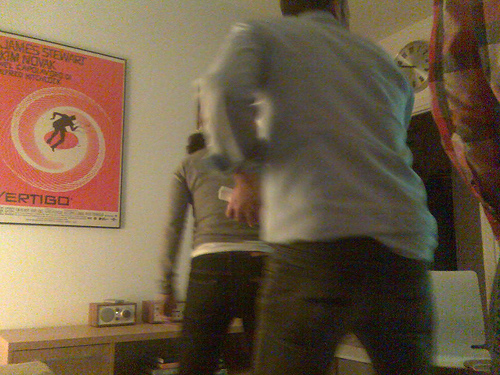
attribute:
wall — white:
[141, 13, 203, 52]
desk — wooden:
[2, 305, 252, 373]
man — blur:
[206, 2, 446, 371]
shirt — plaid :
[198, 10, 445, 263]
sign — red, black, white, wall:
[1, 29, 131, 228]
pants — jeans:
[253, 227, 459, 373]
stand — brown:
[4, 328, 178, 374]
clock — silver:
[395, 40, 438, 83]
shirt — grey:
[304, 120, 333, 230]